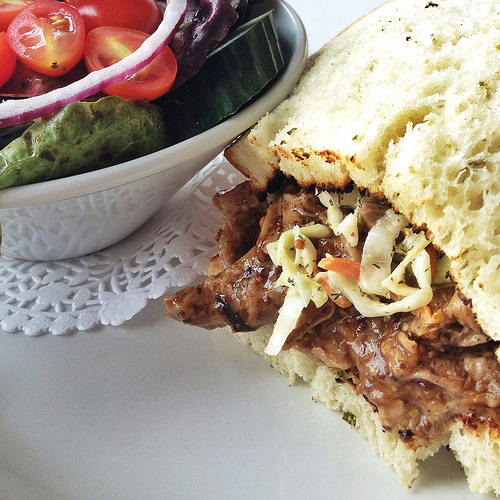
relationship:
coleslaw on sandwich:
[254, 188, 438, 360] [163, 3, 498, 498]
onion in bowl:
[2, 1, 192, 129] [2, 3, 310, 259]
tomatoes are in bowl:
[2, 1, 177, 104] [2, 3, 310, 259]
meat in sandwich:
[163, 167, 499, 452] [163, 3, 498, 498]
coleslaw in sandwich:
[254, 188, 438, 360] [163, 3, 498, 498]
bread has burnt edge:
[219, 4, 498, 371] [267, 142, 499, 367]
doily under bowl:
[1, 157, 247, 341] [2, 3, 310, 259]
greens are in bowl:
[2, 93, 169, 194] [2, 3, 310, 259]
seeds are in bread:
[340, 407, 361, 431] [215, 320, 498, 497]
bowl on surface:
[2, 3, 310, 259] [3, 1, 500, 500]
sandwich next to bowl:
[163, 3, 498, 498] [2, 3, 310, 259]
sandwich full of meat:
[163, 3, 498, 498] [163, 167, 499, 452]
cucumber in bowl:
[160, 9, 286, 140] [2, 3, 310, 259]